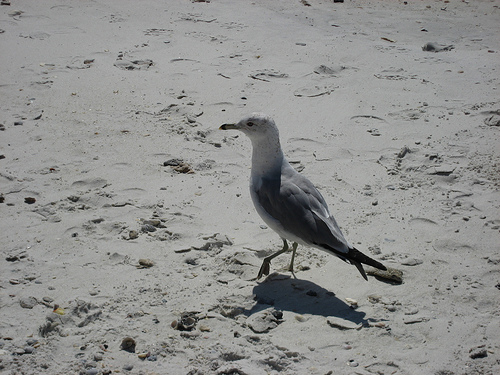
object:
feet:
[252, 240, 284, 283]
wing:
[256, 178, 342, 253]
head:
[218, 113, 280, 141]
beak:
[217, 121, 240, 132]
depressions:
[0, 1, 500, 375]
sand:
[0, 1, 500, 374]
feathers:
[258, 176, 321, 247]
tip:
[219, 121, 240, 133]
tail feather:
[323, 229, 387, 280]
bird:
[217, 112, 391, 284]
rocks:
[33, 279, 42, 285]